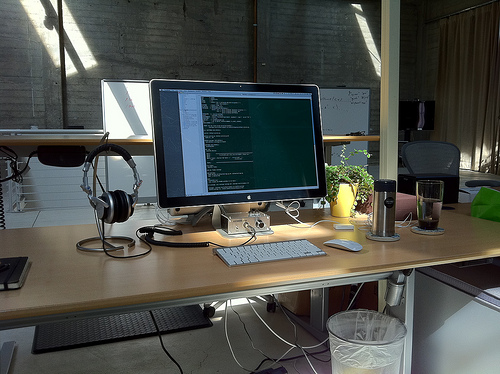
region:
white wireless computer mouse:
[321, 232, 373, 258]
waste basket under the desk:
[314, 302, 421, 372]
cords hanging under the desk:
[206, 282, 416, 372]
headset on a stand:
[73, 127, 149, 272]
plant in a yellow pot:
[317, 145, 377, 229]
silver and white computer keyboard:
[207, 233, 333, 269]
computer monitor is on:
[151, 74, 336, 207]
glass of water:
[413, 162, 452, 239]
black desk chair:
[400, 126, 477, 234]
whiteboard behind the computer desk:
[73, 65, 407, 237]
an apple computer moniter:
[149, 82, 331, 205]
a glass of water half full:
[413, 173, 447, 238]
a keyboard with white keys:
[215, 235, 335, 272]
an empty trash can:
[322, 306, 408, 371]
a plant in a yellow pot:
[330, 146, 370, 224]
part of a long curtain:
[438, 4, 496, 180]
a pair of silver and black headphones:
[75, 140, 143, 227]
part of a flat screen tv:
[400, 98, 442, 132]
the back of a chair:
[403, 136, 464, 196]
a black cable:
[141, 315, 195, 371]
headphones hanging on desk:
[83, 145, 142, 242]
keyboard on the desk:
[221, 237, 321, 260]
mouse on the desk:
[324, 230, 366, 260]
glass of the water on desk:
[406, 178, 442, 239]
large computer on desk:
[144, 75, 325, 224]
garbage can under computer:
[315, 312, 401, 372]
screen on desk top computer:
[175, 95, 300, 183]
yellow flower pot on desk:
[323, 175, 359, 218]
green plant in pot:
[328, 155, 362, 182]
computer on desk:
[138, 72, 327, 262]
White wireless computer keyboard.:
[216, 235, 327, 265]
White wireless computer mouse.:
[320, 232, 361, 247]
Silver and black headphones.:
[72, 143, 142, 223]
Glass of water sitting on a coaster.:
[412, 180, 442, 236]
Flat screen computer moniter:
[150, 82, 329, 204]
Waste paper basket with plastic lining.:
[328, 307, 408, 372]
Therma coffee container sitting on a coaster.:
[372, 175, 398, 243]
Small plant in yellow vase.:
[328, 147, 366, 221]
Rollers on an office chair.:
[202, 293, 292, 318]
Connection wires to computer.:
[201, 292, 323, 372]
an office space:
[13, 49, 498, 371]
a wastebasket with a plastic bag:
[325, 306, 414, 372]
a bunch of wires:
[219, 310, 307, 368]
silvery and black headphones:
[78, 146, 144, 232]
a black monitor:
[146, 81, 331, 211]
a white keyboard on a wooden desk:
[212, 235, 328, 272]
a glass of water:
[408, 177, 448, 227]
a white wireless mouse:
[323, 227, 365, 257]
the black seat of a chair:
[406, 136, 467, 183]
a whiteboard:
[92, 77, 154, 152]